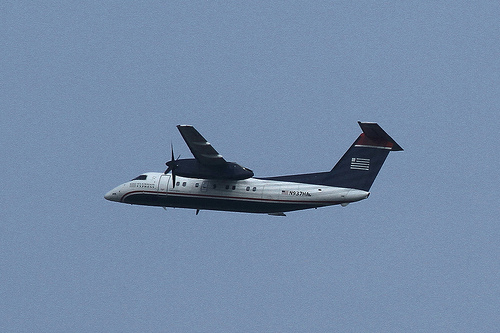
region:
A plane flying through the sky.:
[78, 77, 480, 274]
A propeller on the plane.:
[158, 138, 183, 188]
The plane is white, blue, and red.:
[86, 98, 412, 249]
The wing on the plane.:
[162, 120, 255, 190]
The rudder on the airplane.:
[326, 127, 396, 189]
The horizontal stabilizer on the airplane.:
[346, 105, 416, 155]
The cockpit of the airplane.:
[90, 146, 162, 216]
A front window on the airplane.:
[131, 168, 146, 183]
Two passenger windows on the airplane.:
[241, 177, 261, 192]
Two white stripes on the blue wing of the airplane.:
[172, 137, 232, 167]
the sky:
[285, 297, 325, 331]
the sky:
[346, 252, 382, 312]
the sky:
[326, 269, 367, 321]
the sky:
[362, 297, 382, 327]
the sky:
[362, 250, 392, 300]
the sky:
[324, 229, 357, 284]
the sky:
[326, 273, 349, 329]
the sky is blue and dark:
[234, 275, 250, 295]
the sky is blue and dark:
[262, 261, 276, 281]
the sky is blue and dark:
[247, 287, 278, 305]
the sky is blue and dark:
[278, 290, 297, 312]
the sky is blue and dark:
[278, 280, 290, 297]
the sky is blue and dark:
[282, 125, 288, 141]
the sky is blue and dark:
[284, 300, 297, 322]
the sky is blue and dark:
[286, 313, 296, 316]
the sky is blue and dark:
[262, 306, 279, 331]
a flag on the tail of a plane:
[345, 150, 371, 171]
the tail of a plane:
[326, 112, 411, 207]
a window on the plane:
[250, 183, 259, 193]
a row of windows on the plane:
[171, 176, 261, 197]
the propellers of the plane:
[161, 139, 186, 190]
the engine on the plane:
[161, 137, 263, 188]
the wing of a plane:
[172, 112, 245, 189]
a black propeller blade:
[167, 137, 177, 162]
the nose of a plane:
[99, 180, 124, 208]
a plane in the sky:
[98, 101, 409, 224]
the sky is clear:
[270, 269, 294, 305]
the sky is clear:
[262, 265, 276, 282]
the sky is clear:
[249, 280, 267, 298]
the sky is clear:
[245, 285, 264, 316]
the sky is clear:
[270, 300, 280, 320]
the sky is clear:
[259, 264, 276, 299]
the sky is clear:
[270, 285, 280, 307]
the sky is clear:
[275, 295, 286, 313]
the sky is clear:
[265, 287, 275, 302]